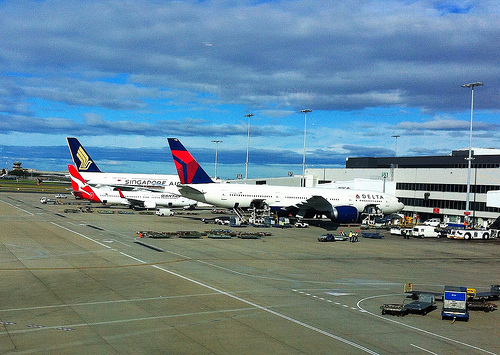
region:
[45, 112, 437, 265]
planes parked on the groun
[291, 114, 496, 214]
building behind the planes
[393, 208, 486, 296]
cars parked in the parking lot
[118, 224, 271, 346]
white lines on parking lot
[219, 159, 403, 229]
the airplanes are white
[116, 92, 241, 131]
the sky is clear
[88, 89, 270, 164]
the clouds are white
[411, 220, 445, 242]
the van is white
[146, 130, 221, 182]
plane has red and blue tail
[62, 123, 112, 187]
plane has yellow and blue tail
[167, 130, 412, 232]
A large red, white, and blue airplane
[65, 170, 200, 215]
A large red and white airplane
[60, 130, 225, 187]
A large white and blue airplane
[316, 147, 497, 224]
An airport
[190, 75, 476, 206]
a line of street lights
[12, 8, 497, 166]
a cloudy, blue sky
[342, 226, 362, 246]
a group of people on the runway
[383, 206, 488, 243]
a group of cars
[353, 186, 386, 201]
branding on the plane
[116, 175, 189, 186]
branding on the plane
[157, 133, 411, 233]
airplane parked at the airport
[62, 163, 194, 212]
brown spot on a giraffe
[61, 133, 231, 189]
brown spot on a giraffe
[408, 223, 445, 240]
white van at an airport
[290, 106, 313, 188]
flood lights on a metal pole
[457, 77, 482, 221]
flood lights on a metal pole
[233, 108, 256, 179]
flood lights on a metal pole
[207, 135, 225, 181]
flood lights on a metal pole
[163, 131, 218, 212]
tail section of an airplane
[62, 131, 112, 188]
tail section of an airplane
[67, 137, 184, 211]
plane flying for Singapore Airlines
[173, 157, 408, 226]
plane flying for Delta Airlines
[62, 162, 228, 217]
plane flying for Qantas Airlines based in Australia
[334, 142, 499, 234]
airport terminal is several stories high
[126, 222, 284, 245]
baggage cars carry bags to and from planes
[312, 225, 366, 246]
baggage handlers chatting it up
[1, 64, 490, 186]
airport is near a body of water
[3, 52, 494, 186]
cloudy day at the airport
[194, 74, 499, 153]
lights to light up the area at night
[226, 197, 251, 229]
airplane boarding ramp is in place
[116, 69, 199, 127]
the sky is clear and blue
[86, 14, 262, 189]
the sky is clear and blue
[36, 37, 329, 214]
the sky is clear and blue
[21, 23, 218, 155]
the sky is clear and blue